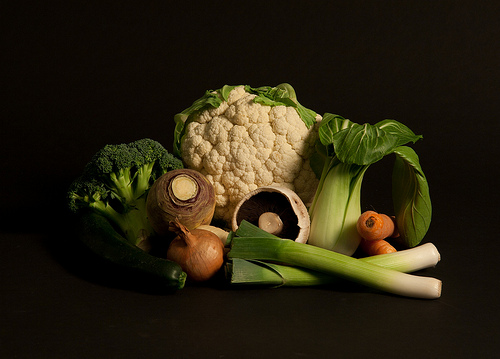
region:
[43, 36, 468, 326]
assortment of green vegetables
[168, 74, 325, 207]
a piece of cauliflower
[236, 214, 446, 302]
a stalk of celery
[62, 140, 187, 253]
a stalk of brocoli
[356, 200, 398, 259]
two chubby orange carrots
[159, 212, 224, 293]
one brown round onion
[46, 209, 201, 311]
one long green cucumber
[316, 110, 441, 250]
leafy greens on vegetable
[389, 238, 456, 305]
white part of celery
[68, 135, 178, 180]
top of broccoli stalk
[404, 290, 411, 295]
part of a root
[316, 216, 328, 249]
edge of a root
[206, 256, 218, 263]
part of an onion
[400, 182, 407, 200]
part of a vegetable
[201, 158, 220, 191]
part of a root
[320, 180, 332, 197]
part of a plant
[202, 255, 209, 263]
edge of an onion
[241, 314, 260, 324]
part of a surface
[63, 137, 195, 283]
Stalk of broccoli.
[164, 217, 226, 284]
Onion next to vegetables.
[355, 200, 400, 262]
Two carrots next to greenery.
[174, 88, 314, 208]
Cauliflower in a group of vegetables.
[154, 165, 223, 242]
Rutabaga upside down.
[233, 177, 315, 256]
Mushroom turned on its side.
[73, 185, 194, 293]
One zucchini in a picture.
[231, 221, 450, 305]
Two pieces of celery on top of another.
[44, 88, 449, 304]
Group of vegetables.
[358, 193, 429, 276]
Orange carrots on the right.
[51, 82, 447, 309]
assorted veggies sitting together on a table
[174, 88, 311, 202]
a big head of cauliflower in the cneter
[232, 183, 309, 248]
a big mushroom sitting on its side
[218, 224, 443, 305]
two leeks laying together on the table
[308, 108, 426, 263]
a veggie with many long leaves on it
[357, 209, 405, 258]
the carrots laying together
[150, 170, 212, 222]
a single turnip next to the broccoli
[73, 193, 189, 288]
some zucchini laying on the table too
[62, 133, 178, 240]
a single head of broccoli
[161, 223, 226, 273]
and finally, one tiny little onion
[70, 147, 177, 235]
Broccoli in dramatic lighting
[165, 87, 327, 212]
The cauliflower is the largest of the vegetables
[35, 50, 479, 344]
still life of vegetables on black background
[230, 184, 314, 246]
the mushroom is on its side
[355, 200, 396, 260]
The ends of two carrots are visible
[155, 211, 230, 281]
The onion has a reflection of a light on it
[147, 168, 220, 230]
brown cylindrical vegetable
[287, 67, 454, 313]
highlights on right side of vegetables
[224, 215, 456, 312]
Two nearly identical green vegetables lie on their side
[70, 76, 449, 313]
green, white, and orange color palette